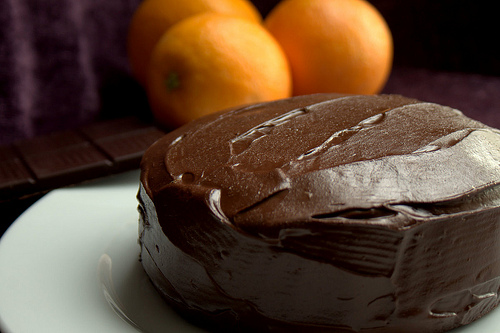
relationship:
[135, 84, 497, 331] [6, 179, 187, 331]
cake on plate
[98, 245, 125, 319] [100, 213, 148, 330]
light reflected on plate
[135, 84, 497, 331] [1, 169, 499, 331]
cake on plate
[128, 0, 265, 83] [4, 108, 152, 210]
orange on table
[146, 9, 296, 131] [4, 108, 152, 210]
orange on table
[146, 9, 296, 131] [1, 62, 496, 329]
orange on table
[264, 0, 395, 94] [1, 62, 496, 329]
orange on table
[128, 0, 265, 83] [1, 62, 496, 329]
orange on table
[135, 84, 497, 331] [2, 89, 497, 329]
cake on plate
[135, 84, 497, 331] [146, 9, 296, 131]
cake front orange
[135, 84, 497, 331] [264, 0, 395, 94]
cake front orange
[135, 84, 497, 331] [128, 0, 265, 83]
cake front orange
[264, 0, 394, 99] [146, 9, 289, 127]
orange sideways orange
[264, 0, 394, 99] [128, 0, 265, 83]
orange sideways orange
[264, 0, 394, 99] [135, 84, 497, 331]
orange beside cake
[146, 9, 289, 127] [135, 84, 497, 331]
orange beside cake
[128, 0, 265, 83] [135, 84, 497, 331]
orange beside cake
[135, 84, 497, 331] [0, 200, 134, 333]
cake over white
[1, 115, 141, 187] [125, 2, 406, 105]
bars left of oranges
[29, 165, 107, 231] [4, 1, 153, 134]
left corner of table